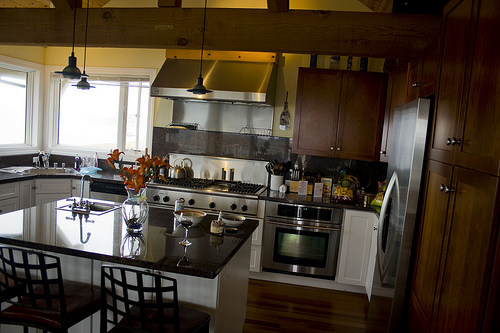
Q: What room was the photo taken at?
A: It was taken at the kitchen.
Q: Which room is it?
A: It is a kitchen.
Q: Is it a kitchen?
A: Yes, it is a kitchen.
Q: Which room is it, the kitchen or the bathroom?
A: It is the kitchen.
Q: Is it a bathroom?
A: No, it is a kitchen.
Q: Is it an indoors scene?
A: Yes, it is indoors.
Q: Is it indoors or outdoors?
A: It is indoors.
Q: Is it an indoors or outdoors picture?
A: It is indoors.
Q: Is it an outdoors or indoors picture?
A: It is indoors.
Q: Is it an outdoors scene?
A: No, it is indoors.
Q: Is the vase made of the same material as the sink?
A: No, the vase is made of glass and the sink is made of metal.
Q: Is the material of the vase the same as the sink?
A: No, the vase is made of glass and the sink is made of metal.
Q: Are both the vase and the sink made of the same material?
A: No, the vase is made of glass and the sink is made of metal.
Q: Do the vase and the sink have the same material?
A: No, the vase is made of glass and the sink is made of metal.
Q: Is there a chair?
A: Yes, there is a chair.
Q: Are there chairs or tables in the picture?
A: Yes, there is a chair.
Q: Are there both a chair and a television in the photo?
A: No, there is a chair but no televisions.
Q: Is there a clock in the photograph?
A: No, there are no clocks.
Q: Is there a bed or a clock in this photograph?
A: No, there are no clocks or beds.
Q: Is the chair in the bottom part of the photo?
A: Yes, the chair is in the bottom of the image.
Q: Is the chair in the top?
A: No, the chair is in the bottom of the image.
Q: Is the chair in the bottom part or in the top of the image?
A: The chair is in the bottom of the image.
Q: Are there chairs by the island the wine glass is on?
A: Yes, there is a chair by the island.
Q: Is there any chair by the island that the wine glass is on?
A: Yes, there is a chair by the island.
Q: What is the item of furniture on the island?
A: The piece of furniture is a chair.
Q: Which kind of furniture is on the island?
A: The piece of furniture is a chair.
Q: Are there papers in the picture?
A: No, there are no papers.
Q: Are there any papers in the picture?
A: No, there are no papers.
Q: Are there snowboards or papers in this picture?
A: No, there are no papers or snowboards.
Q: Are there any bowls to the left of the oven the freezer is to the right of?
A: Yes, there are bowls to the left of the oven.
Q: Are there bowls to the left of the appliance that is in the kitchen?
A: Yes, there are bowls to the left of the oven.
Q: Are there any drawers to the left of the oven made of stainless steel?
A: No, there are bowls to the left of the oven.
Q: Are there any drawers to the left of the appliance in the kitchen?
A: No, there are bowls to the left of the oven.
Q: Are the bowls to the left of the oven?
A: Yes, the bowls are to the left of the oven.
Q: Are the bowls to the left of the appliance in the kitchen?
A: Yes, the bowls are to the left of the oven.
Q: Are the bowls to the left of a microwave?
A: No, the bowls are to the left of the oven.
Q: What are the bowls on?
A: The bowls are on the island.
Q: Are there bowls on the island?
A: Yes, there are bowls on the island.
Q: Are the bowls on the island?
A: Yes, the bowls are on the island.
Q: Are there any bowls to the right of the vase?
A: Yes, there are bowls to the right of the vase.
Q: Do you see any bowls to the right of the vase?
A: Yes, there are bowls to the right of the vase.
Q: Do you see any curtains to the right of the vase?
A: No, there are bowls to the right of the vase.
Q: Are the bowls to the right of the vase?
A: Yes, the bowls are to the right of the vase.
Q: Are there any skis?
A: No, there are no skis.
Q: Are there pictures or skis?
A: No, there are no skis or pictures.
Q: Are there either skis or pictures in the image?
A: No, there are no skis or pictures.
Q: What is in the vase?
A: The flowers are in the vase.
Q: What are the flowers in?
A: The flowers are in the vase.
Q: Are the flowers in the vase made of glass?
A: Yes, the flowers are in the vase.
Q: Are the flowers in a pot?
A: No, the flowers are in the vase.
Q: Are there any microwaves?
A: No, there are no microwaves.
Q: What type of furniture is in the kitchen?
A: The pieces of furniture are cupboards.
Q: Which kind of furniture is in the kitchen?
A: The pieces of furniture are cupboards.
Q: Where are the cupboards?
A: The cupboards are in the kitchen.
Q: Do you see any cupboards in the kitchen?
A: Yes, there are cupboards in the kitchen.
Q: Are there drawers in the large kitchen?
A: No, there are cupboards in the kitchen.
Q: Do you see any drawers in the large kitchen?
A: No, there are cupboards in the kitchen.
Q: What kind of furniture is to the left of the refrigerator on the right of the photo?
A: The pieces of furniture are cupboards.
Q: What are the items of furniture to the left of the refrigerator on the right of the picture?
A: The pieces of furniture are cupboards.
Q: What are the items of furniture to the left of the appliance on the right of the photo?
A: The pieces of furniture are cupboards.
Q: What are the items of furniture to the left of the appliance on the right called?
A: The pieces of furniture are cupboards.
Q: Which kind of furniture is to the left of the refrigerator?
A: The pieces of furniture are cupboards.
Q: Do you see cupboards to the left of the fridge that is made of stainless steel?
A: Yes, there are cupboards to the left of the fridge.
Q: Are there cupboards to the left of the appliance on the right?
A: Yes, there are cupboards to the left of the fridge.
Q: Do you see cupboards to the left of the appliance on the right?
A: Yes, there are cupboards to the left of the fridge.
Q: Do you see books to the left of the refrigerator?
A: No, there are cupboards to the left of the refrigerator.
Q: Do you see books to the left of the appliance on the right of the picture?
A: No, there are cupboards to the left of the refrigerator.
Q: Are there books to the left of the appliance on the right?
A: No, there are cupboards to the left of the refrigerator.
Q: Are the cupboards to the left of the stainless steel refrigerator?
A: Yes, the cupboards are to the left of the freezer.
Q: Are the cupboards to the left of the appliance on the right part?
A: Yes, the cupboards are to the left of the freezer.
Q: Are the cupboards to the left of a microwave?
A: No, the cupboards are to the left of the freezer.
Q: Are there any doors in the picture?
A: Yes, there is a door.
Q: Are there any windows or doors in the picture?
A: Yes, there is a door.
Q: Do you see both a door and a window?
A: Yes, there are both a door and a window.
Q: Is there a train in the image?
A: No, there are no trains.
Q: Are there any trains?
A: No, there are no trains.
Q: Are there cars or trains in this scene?
A: No, there are no trains or cars.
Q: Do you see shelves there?
A: No, there are no shelves.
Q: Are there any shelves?
A: No, there are no shelves.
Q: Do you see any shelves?
A: No, there are no shelves.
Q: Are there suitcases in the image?
A: No, there are no suitcases.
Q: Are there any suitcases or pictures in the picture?
A: No, there are no suitcases or pictures.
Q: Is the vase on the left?
A: Yes, the vase is on the left of the image.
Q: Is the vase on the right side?
A: No, the vase is on the left of the image.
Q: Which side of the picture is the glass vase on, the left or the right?
A: The vase is on the left of the image.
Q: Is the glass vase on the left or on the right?
A: The vase is on the left of the image.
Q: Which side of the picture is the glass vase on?
A: The vase is on the left of the image.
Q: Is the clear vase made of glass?
A: Yes, the vase is made of glass.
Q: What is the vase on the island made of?
A: The vase is made of glass.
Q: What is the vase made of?
A: The vase is made of glass.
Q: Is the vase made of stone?
A: No, the vase is made of glass.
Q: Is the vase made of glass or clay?
A: The vase is made of glass.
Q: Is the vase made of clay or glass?
A: The vase is made of glass.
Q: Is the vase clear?
A: Yes, the vase is clear.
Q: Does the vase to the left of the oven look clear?
A: Yes, the vase is clear.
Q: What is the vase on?
A: The vase is on the island.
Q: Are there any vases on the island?
A: Yes, there is a vase on the island.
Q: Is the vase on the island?
A: Yes, the vase is on the island.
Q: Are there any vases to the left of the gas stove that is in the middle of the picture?
A: Yes, there is a vase to the left of the gas stove.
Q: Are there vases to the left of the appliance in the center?
A: Yes, there is a vase to the left of the gas stove.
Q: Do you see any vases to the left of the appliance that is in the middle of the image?
A: Yes, there is a vase to the left of the gas stove.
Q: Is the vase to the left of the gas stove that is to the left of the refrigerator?
A: Yes, the vase is to the left of the gas stove.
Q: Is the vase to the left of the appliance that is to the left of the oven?
A: Yes, the vase is to the left of the gas stove.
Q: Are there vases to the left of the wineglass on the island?
A: Yes, there is a vase to the left of the wineglass.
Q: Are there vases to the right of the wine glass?
A: No, the vase is to the left of the wine glass.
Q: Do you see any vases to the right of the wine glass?
A: No, the vase is to the left of the wine glass.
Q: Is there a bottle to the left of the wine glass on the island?
A: No, there is a vase to the left of the wine glass.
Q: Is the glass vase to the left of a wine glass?
A: Yes, the vase is to the left of a wine glass.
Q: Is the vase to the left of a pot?
A: No, the vase is to the left of a wine glass.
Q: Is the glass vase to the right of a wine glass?
A: No, the vase is to the left of a wine glass.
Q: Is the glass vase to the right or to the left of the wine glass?
A: The vase is to the left of the wine glass.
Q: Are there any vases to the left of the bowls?
A: Yes, there is a vase to the left of the bowls.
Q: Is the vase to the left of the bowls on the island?
A: Yes, the vase is to the left of the bowls.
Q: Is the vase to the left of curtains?
A: No, the vase is to the left of the bowls.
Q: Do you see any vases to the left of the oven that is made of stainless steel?
A: Yes, there is a vase to the left of the oven.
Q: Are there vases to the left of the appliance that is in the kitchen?
A: Yes, there is a vase to the left of the oven.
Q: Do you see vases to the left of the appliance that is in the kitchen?
A: Yes, there is a vase to the left of the oven.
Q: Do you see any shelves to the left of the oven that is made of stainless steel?
A: No, there is a vase to the left of the oven.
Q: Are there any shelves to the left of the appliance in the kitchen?
A: No, there is a vase to the left of the oven.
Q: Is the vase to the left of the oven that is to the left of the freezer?
A: Yes, the vase is to the left of the oven.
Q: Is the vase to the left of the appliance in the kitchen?
A: Yes, the vase is to the left of the oven.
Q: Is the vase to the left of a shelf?
A: No, the vase is to the left of the oven.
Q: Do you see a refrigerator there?
A: Yes, there is a refrigerator.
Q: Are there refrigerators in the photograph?
A: Yes, there is a refrigerator.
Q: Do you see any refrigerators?
A: Yes, there is a refrigerator.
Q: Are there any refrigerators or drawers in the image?
A: Yes, there is a refrigerator.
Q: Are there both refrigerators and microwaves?
A: No, there is a refrigerator but no microwaves.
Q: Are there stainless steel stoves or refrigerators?
A: Yes, there is a stainless steel refrigerator.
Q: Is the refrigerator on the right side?
A: Yes, the refrigerator is on the right of the image.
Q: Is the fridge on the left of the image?
A: No, the fridge is on the right of the image.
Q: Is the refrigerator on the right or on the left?
A: The refrigerator is on the right of the image.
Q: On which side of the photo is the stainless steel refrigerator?
A: The freezer is on the right of the image.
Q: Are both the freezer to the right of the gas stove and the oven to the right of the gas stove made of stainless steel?
A: Yes, both the refrigerator and the oven are made of stainless steel.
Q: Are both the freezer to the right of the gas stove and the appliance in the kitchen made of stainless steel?
A: Yes, both the refrigerator and the oven are made of stainless steel.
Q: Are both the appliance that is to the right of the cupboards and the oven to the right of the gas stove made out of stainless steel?
A: Yes, both the refrigerator and the oven are made of stainless steel.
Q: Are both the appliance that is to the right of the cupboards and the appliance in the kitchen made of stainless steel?
A: Yes, both the refrigerator and the oven are made of stainless steel.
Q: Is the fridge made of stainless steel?
A: Yes, the fridge is made of stainless steel.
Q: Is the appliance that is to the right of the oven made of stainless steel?
A: Yes, the fridge is made of stainless steel.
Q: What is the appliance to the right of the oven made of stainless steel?
A: The appliance is a refrigerator.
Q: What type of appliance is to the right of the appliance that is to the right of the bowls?
A: The appliance is a refrigerator.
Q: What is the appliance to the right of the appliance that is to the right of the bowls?
A: The appliance is a refrigerator.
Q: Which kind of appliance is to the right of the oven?
A: The appliance is a refrigerator.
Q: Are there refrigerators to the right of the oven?
A: Yes, there is a refrigerator to the right of the oven.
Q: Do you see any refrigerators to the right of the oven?
A: Yes, there is a refrigerator to the right of the oven.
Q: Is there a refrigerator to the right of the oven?
A: Yes, there is a refrigerator to the right of the oven.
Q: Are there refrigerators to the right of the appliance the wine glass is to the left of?
A: Yes, there is a refrigerator to the right of the oven.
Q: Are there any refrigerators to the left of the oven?
A: No, the refrigerator is to the right of the oven.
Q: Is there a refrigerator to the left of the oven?
A: No, the refrigerator is to the right of the oven.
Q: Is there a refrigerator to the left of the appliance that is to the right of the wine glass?
A: No, the refrigerator is to the right of the oven.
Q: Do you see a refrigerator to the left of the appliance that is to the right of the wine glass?
A: No, the refrigerator is to the right of the oven.